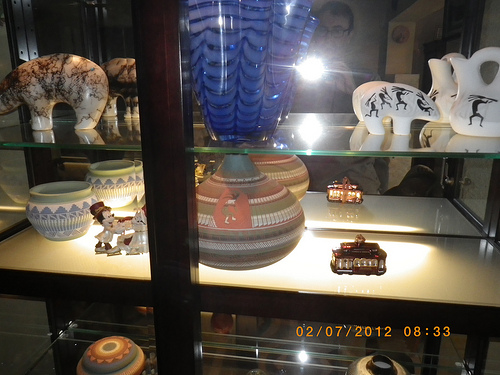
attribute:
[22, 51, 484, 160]
figures — DISNEY ACTION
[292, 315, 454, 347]
date — TAKEN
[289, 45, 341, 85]
flash — REFLECTION 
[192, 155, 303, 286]
pottery — striped, round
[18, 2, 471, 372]
wall — mirrored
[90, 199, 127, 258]
mickey mouse — wearing ice skates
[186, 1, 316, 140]
glass art — clear and blue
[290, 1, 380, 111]
man — taking a picture of the items in case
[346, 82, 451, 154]
bear — white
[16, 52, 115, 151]
bear — marble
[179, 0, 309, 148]
glass — blue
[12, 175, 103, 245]
pottery — green, blue, white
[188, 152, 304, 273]
pottery — white, reddish, tan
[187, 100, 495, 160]
shelf — glassy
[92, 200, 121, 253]
sculpture — tiny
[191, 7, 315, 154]
glass — big, blue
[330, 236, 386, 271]
house — small, tiny, brown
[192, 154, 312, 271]
bowl — red, green, white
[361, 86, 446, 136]
sculpture — white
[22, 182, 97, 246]
bowl — green, white, blue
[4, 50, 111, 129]
bear — brown